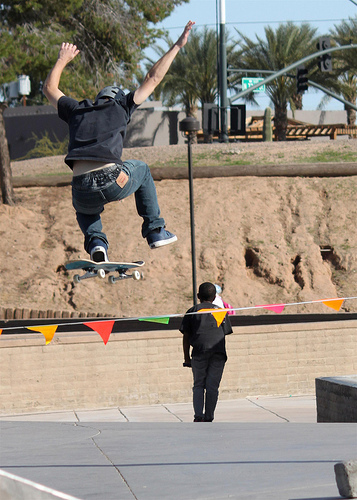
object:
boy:
[179, 279, 233, 423]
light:
[228, 103, 248, 134]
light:
[297, 66, 308, 94]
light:
[319, 36, 334, 71]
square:
[118, 405, 181, 426]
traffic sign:
[241, 76, 267, 94]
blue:
[68, 165, 130, 212]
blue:
[136, 188, 157, 220]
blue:
[82, 219, 104, 240]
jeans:
[70, 161, 179, 262]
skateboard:
[57, 256, 146, 285]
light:
[178, 114, 200, 315]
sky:
[1, 0, 354, 107]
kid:
[178, 278, 235, 423]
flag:
[28, 315, 58, 349]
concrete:
[0, 419, 357, 496]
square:
[76, 407, 126, 420]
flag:
[133, 314, 173, 331]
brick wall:
[1, 318, 355, 411]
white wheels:
[132, 270, 141, 282]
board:
[54, 256, 147, 284]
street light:
[205, 102, 247, 137]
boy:
[45, 9, 194, 260]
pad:
[191, 404, 219, 427]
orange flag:
[318, 298, 347, 313]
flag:
[257, 300, 289, 315]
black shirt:
[179, 304, 233, 361]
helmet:
[95, 82, 127, 98]